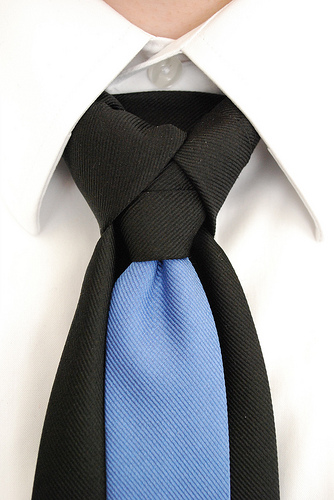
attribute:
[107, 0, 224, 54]
man's race — white